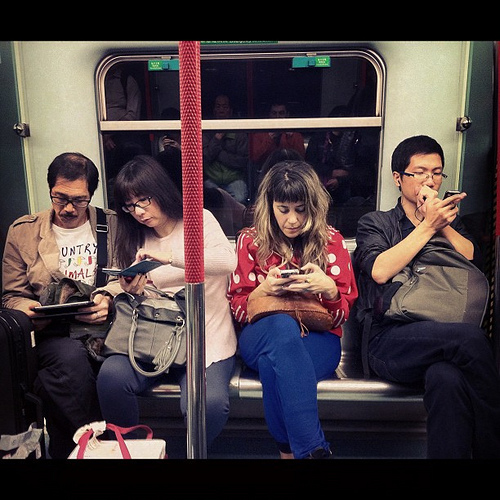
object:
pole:
[176, 41, 209, 460]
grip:
[177, 40, 204, 284]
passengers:
[98, 152, 239, 450]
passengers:
[228, 157, 356, 458]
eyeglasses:
[50, 193, 92, 210]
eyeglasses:
[122, 197, 152, 212]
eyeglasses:
[401, 168, 449, 183]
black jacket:
[356, 201, 476, 332]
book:
[101, 261, 158, 278]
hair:
[267, 161, 323, 199]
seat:
[135, 373, 442, 430]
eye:
[278, 206, 290, 215]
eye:
[412, 168, 425, 178]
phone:
[440, 187, 459, 218]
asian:
[353, 115, 494, 409]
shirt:
[226, 221, 359, 329]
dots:
[232, 271, 241, 285]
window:
[97, 56, 386, 174]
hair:
[44, 154, 100, 197]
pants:
[235, 310, 340, 460]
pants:
[93, 341, 238, 461]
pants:
[5, 317, 106, 438]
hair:
[392, 134, 452, 169]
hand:
[115, 269, 147, 296]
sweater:
[123, 200, 248, 376]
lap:
[266, 311, 304, 359]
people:
[0, 141, 500, 480]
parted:
[282, 158, 292, 182]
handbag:
[104, 282, 189, 377]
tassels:
[147, 318, 184, 374]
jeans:
[235, 312, 342, 452]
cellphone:
[442, 187, 463, 198]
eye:
[295, 202, 306, 213]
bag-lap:
[377, 235, 491, 326]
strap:
[93, 204, 108, 286]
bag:
[247, 290, 336, 332]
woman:
[44, 122, 340, 428]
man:
[3, 151, 127, 433]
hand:
[427, 190, 459, 227]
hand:
[413, 185, 438, 215]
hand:
[289, 262, 330, 294]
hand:
[258, 269, 295, 296]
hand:
[128, 247, 170, 266]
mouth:
[279, 224, 301, 233]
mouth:
[140, 217, 157, 224]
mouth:
[58, 211, 77, 220]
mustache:
[57, 210, 79, 218]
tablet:
[24, 288, 93, 324]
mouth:
[415, 182, 438, 203]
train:
[6, 5, 481, 498]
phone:
[273, 266, 303, 284]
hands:
[285, 262, 331, 296]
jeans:
[374, 320, 500, 456]